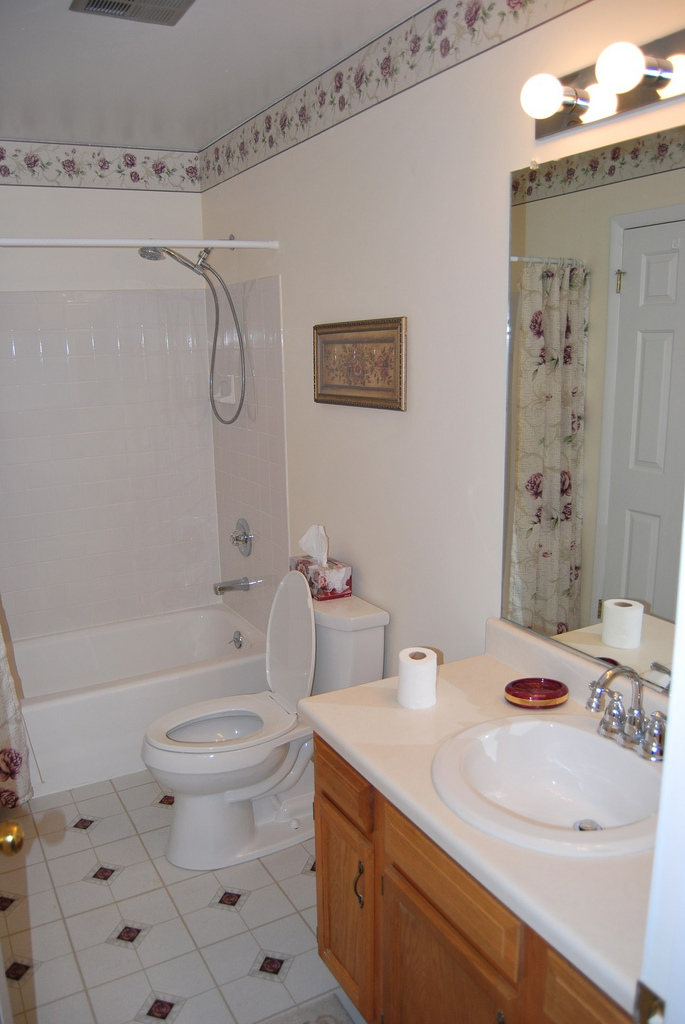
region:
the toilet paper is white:
[395, 640, 439, 714]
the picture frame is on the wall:
[308, 314, 409, 413]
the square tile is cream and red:
[46, 830, 163, 923]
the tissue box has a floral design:
[290, 527, 351, 602]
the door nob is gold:
[2, 828, 26, 856]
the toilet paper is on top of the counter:
[389, 647, 442, 714]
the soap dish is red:
[501, 673, 571, 714]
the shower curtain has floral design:
[509, 258, 597, 631]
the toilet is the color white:
[143, 570, 389, 877]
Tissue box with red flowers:
[284, 528, 360, 599]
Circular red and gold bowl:
[502, 667, 570, 709]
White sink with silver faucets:
[432, 651, 668, 855]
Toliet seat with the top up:
[110, 565, 393, 868]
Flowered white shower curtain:
[509, 254, 596, 636]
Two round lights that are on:
[502, 34, 683, 139]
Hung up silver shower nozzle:
[133, 224, 279, 427]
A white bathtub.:
[3, 603, 270, 800]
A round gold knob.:
[0, 821, 26, 856]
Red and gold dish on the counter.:
[505, 676, 569, 710]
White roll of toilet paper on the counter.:
[396, 645, 437, 709]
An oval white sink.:
[428, 710, 660, 854]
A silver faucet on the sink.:
[586, 663, 645, 747]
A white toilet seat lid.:
[263, 572, 315, 708]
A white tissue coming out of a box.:
[297, 524, 329, 568]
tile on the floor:
[249, 951, 284, 973]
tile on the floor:
[129, 989, 169, 1016]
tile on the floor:
[109, 923, 136, 946]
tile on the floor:
[91, 869, 114, 887]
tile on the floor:
[56, 815, 98, 832]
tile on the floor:
[156, 795, 174, 816]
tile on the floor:
[16, 966, 36, 974]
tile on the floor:
[319, 982, 325, 989]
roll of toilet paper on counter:
[394, 643, 443, 713]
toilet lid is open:
[126, 534, 400, 877]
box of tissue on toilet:
[285, 520, 356, 611]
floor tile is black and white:
[0, 753, 373, 1022]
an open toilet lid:
[265, 565, 312, 705]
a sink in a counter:
[430, 713, 658, 852]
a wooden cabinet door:
[314, 795, 374, 1017]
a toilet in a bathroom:
[139, 570, 385, 870]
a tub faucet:
[214, 581, 256, 594]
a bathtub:
[6, 593, 273, 809]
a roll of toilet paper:
[399, 645, 436, 707]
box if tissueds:
[289, 525, 352, 600]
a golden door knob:
[0, 820, 22, 854]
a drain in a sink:
[575, 816, 604, 830]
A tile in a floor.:
[15, 952, 83, 1013]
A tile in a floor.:
[84, 966, 151, 1021]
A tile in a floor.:
[174, 986, 231, 1022]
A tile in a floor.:
[75, 787, 126, 823]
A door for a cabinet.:
[310, 792, 373, 1021]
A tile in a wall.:
[66, 327, 94, 358]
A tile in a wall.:
[74, 404, 100, 432]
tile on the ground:
[101, 888, 288, 979]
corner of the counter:
[255, 681, 378, 765]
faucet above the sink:
[550, 654, 661, 747]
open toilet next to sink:
[92, 663, 330, 803]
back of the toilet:
[228, 549, 342, 726]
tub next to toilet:
[5, 567, 251, 720]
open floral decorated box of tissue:
[291, 518, 355, 598]